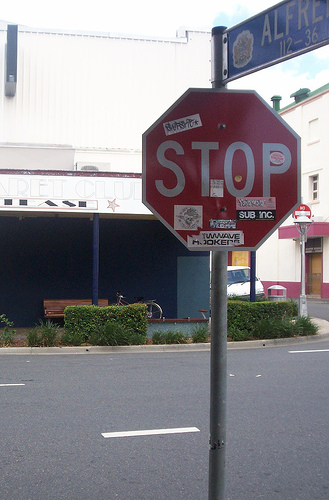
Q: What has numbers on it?
A: Street sign.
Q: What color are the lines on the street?
A: White.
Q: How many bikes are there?
A: 1.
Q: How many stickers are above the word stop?
A: 1.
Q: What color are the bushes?
A: Green.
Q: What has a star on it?
A: Building sign.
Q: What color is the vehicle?
A: White.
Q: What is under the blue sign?
A: Stop sign.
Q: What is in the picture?
A: Part of a red stop sign.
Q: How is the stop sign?
A: Red and octagon.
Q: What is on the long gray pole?
A: A stop sign.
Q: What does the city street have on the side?
A: A stop sign.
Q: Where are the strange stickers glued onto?
A: The stop sign.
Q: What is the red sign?
A: Stop sign.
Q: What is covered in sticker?
A: Stop sign.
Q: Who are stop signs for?
A: Cars.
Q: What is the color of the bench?
A: Brown.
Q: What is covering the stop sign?
A: Stickers.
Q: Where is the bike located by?
A: The bench.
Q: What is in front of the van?
A: Post.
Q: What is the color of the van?
A: White.